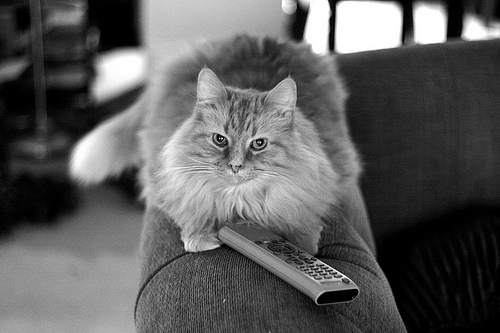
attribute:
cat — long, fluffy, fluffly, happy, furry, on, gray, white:
[79, 23, 362, 273]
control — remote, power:
[200, 165, 362, 307]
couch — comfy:
[383, 63, 477, 236]